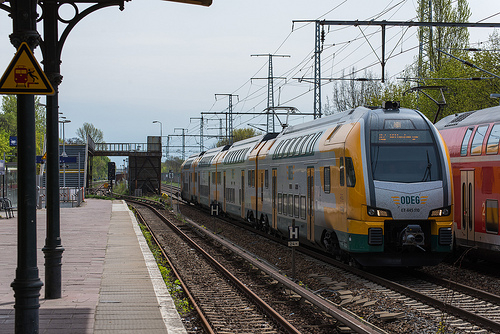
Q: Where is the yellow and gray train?
A: On the train tracks.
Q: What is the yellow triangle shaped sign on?
A: Pole.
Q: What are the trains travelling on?
A: Tracks.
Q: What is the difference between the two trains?
A: Color.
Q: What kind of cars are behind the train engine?
A: Passenger cars.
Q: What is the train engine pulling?
A: Cars.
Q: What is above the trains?
A: Power lines.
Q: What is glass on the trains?
A: Windows.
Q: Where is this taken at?
A: Train station.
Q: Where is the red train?
A: On the right.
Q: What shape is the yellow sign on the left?
A: A triangle.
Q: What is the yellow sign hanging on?
A: A pole.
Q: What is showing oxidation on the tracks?
A: Rust.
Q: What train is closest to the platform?
A: Yellow and silver one.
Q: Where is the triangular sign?
A: On post on the left.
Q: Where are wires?
A: Over the trains.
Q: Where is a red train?
A: Left of yellow and silver train.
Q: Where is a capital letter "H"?
A: Left of the yellow and silver train.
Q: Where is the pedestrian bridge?
A: Far end of platform.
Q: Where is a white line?
A: Edge of platform.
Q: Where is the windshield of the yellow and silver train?
A: Above the gray area on the front.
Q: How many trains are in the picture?
A: Two.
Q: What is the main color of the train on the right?
A: Red.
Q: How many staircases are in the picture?
A: One.